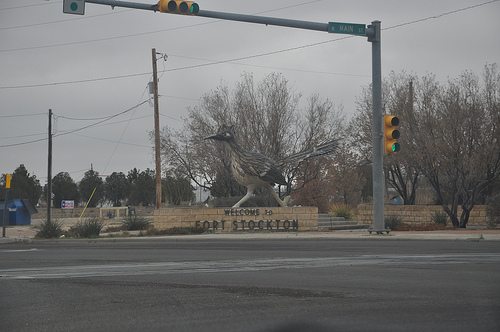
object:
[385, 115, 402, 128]
street light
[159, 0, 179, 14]
street light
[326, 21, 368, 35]
sign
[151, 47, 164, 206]
light pole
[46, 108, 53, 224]
light pole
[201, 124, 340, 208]
statue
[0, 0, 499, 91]
electrical lines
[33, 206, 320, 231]
wall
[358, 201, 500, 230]
wall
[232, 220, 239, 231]
letters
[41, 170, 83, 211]
trees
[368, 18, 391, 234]
pole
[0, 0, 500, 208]
sky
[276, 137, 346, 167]
tail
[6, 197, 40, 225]
dumpster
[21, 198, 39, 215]
lid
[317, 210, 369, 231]
stairs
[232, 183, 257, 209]
leg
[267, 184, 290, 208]
leg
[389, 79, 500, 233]
trees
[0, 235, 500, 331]
main street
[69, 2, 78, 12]
circle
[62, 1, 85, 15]
sign